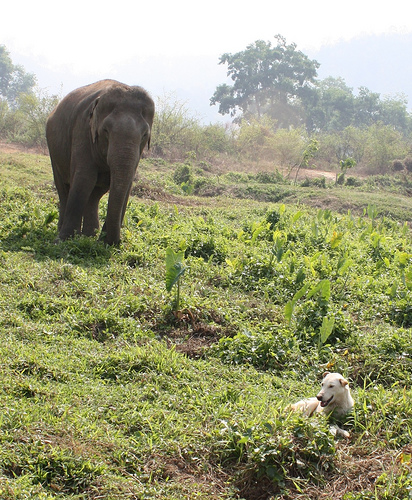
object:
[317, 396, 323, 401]
nose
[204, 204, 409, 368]
vegetation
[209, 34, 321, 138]
trees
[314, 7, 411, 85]
horizon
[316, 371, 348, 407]
head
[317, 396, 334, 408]
mouth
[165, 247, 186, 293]
leaf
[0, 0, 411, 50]
cloud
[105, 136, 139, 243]
trunk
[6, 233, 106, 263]
shadow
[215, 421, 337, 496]
tuft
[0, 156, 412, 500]
grass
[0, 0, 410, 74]
sky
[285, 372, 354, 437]
dog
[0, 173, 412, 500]
ground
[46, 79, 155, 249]
elephant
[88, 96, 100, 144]
ears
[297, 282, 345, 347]
plant.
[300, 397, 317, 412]
fur